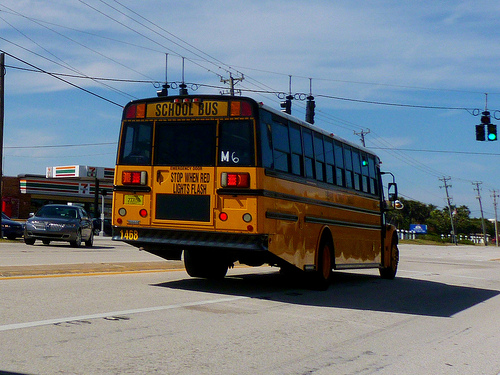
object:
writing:
[199, 184, 206, 194]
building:
[4, 164, 113, 232]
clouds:
[461, 0, 496, 27]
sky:
[0, 0, 497, 221]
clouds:
[244, 37, 276, 64]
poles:
[441, 179, 456, 243]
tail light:
[239, 175, 251, 186]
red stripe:
[55, 173, 76, 179]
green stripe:
[53, 169, 76, 174]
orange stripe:
[54, 166, 78, 171]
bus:
[107, 92, 401, 280]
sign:
[414, 222, 426, 232]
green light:
[475, 123, 497, 139]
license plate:
[122, 194, 144, 206]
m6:
[219, 149, 240, 164]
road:
[425, 245, 491, 281]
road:
[420, 276, 489, 313]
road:
[360, 309, 485, 366]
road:
[162, 292, 309, 356]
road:
[25, 260, 126, 351]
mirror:
[389, 183, 398, 204]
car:
[22, 204, 91, 246]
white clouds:
[288, 7, 326, 56]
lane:
[12, 264, 498, 374]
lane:
[1, 237, 449, 323]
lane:
[7, 206, 426, 273]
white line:
[15, 297, 193, 329]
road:
[35, 277, 482, 365]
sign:
[52, 163, 79, 180]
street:
[1, 231, 484, 371]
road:
[1, 236, 484, 370]